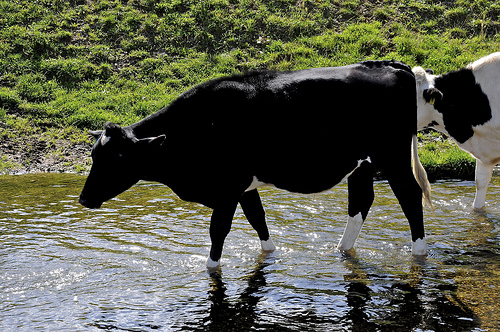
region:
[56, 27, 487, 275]
cows walking in the water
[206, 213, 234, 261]
leg of the cow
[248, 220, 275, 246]
leg of the cow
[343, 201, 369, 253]
leg of the cow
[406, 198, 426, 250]
leg of the cow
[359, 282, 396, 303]
ripple in the water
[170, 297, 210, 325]
ripple in the water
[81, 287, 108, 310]
ripple in the water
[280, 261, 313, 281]
ripple in the water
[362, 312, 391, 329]
ripple in the water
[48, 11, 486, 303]
two cows wade into the water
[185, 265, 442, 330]
shadow of the cow in the water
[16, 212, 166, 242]
ripples in the stream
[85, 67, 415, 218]
black cow with white markings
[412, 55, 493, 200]
white cow with black markings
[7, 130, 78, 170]
stones at the edge of the stream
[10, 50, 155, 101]
vegetation along the bank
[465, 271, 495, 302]
clear water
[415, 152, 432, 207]
cow's tail hanging down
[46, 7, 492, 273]
cows enter a stream of water on a sunny day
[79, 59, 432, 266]
A cow walking in a stream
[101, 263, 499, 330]
Reflection of an animal in a stream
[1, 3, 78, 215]
Grass growing on the bank of a stream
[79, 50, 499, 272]
Two bovine walking in the water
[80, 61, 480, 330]
A cow and its reflection in the water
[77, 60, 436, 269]
A cow wading in a brook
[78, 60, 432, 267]
A black and white cow in the water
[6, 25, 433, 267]
A cow near the riverbank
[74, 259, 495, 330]
The reflection of a cow on the water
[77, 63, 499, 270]
Two bovine walking in a brook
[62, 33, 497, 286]
two cows standing in the water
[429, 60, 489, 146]
black spot on the cow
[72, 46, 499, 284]
two black and white cows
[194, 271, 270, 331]
reflectoin in the water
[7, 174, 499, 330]
shallow body of water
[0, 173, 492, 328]
green body of water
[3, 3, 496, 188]
green grass along the shoreline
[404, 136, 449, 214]
whire hair on the tail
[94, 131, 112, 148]
white spot on the head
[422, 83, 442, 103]
black ear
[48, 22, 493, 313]
The cows are walking in water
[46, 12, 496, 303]
The cows are walking through a creek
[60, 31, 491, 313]
The cow's feet are getting wet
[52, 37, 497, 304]
Two cows are walking around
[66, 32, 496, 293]
One cow is following another cow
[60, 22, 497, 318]
The cows are taking a walk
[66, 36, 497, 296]
The cows are looking for grass to eat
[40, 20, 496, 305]
The cows are on a farm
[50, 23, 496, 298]
The cows are enjoying the sunshine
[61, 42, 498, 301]
A male and a female cow